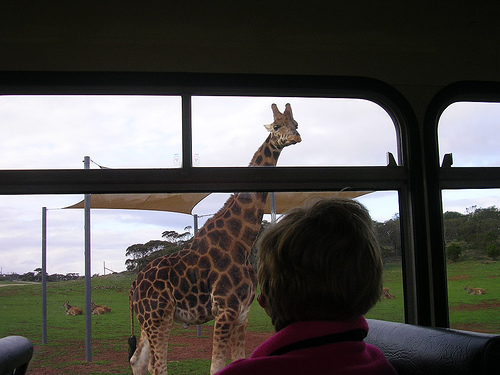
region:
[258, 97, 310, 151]
the head of a giraffe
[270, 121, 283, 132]
the eye of a giraffe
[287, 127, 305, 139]
the nose of a giraffe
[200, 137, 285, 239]
the neck of a giraffe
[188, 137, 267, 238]
the mane of a giraffe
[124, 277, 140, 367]
the tail of a giraffe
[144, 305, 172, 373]
the hind legs of a giraffe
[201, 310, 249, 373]
the front legs of a giraffe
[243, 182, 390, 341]
the head of a person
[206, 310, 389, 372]
a pink sweater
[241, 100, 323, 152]
a giraffees head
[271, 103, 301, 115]
giraffees has two ears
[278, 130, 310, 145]
the giraffees mouth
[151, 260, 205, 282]
giraffee has spots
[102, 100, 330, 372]
a griaffee is tall looking at the camera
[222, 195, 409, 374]
a person wearing a purple jacket is looking out the window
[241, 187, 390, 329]
a person with short brown hair is looking at the girafeee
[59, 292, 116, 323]
two giraffees laying down in grass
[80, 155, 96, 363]
a pole in the ground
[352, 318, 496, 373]
a person sitting in a seat looking out at the animals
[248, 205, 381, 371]
back of a woman's head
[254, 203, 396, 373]
woman with short blond hair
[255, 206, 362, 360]
woman wearing a pink jacket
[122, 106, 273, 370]
giraffe standing on grass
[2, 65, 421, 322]
window of a bus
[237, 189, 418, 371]
woman looking out the window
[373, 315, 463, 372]
black bus seat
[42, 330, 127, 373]
patch of dirt in grass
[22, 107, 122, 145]
cloudy sky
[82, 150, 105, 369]
silver metal post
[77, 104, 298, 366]
the giraffe has stripes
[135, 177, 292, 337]
the giraffe has stripes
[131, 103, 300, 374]
a giraffe at a safari park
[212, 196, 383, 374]
a person watching the animals from the safari vehicle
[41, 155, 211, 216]
a shade canopy behind the giraffe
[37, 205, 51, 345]
metal poles supporting the shade canopies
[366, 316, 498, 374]
the safari vehicle has black bench seats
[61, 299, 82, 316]
wildebeest are laying in the grass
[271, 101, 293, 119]
the giraffe has two horns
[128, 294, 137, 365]
the giraffes tail has long black hair at the end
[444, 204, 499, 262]
tall trees border the field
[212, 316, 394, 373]
the passenger is wearing a red jacket